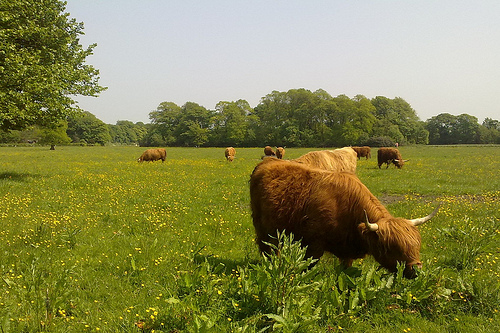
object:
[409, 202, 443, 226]
horns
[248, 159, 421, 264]
fur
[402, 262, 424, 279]
nose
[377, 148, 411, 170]
cow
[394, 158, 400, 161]
horns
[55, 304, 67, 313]
flower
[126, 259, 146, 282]
weed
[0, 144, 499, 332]
field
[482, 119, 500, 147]
trees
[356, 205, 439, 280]
head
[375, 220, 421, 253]
hair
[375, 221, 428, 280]
face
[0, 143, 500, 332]
grass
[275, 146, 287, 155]
head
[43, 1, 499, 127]
sky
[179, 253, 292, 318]
shadow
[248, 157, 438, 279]
animal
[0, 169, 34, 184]
shadow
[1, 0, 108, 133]
tree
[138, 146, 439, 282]
group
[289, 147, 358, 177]
animal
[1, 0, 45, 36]
leaves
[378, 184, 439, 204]
dirt